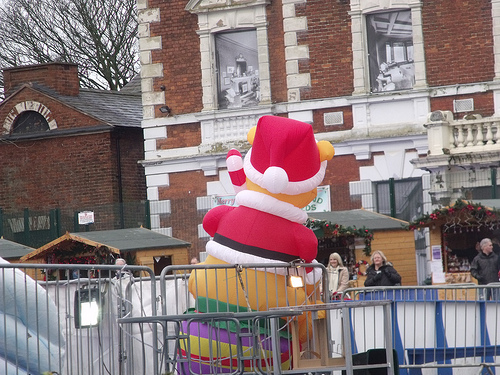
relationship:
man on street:
[473, 226, 498, 291] [8, 232, 479, 367]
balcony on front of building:
[368, 94, 495, 175] [130, 1, 498, 272]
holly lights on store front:
[401, 196, 498, 233] [420, 110, 498, 220]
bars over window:
[371, 177, 423, 209] [358, 175, 430, 227]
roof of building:
[0, 64, 147, 131] [0, 62, 149, 249]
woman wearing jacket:
[361, 249, 402, 288] [362, 263, 402, 292]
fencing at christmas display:
[5, 257, 497, 371] [10, 118, 499, 373]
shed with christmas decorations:
[313, 200, 420, 288] [410, 195, 499, 233]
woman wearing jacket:
[361, 249, 402, 288] [360, 265, 396, 285]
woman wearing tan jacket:
[319, 252, 350, 303] [321, 265, 354, 293]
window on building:
[212, 26, 263, 112] [130, 1, 498, 272]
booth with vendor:
[399, 196, 499, 301] [469, 235, 499, 283]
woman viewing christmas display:
[361, 249, 402, 288] [172, 114, 337, 373]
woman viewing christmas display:
[321, 248, 352, 302] [172, 114, 337, 373]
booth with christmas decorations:
[429, 209, 484, 283] [400, 187, 499, 233]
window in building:
[214, 29, 259, 95] [130, 1, 498, 272]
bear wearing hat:
[220, 109, 324, 254] [242, 112, 330, 196]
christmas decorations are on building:
[400, 187, 499, 233] [329, 1, 496, 280]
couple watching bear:
[327, 249, 402, 294] [189, 114, 337, 350]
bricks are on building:
[36, 114, 133, 195] [1, 45, 147, 239]